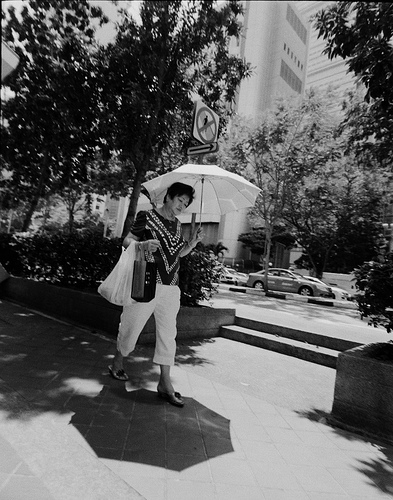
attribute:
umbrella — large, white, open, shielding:
[138, 140, 277, 231]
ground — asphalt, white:
[43, 395, 149, 497]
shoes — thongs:
[97, 348, 195, 414]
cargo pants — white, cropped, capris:
[108, 261, 213, 371]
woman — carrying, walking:
[85, 173, 206, 429]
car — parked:
[231, 245, 347, 310]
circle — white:
[171, 101, 241, 162]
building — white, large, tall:
[207, 4, 387, 206]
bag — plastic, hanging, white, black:
[105, 239, 177, 309]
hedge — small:
[17, 195, 221, 290]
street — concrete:
[5, 296, 389, 500]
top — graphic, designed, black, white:
[125, 212, 220, 284]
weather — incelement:
[12, 5, 389, 139]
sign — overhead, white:
[180, 90, 256, 155]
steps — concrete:
[217, 293, 392, 383]